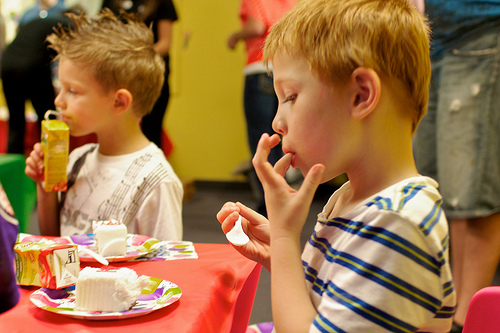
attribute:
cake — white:
[92, 219, 126, 256]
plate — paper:
[62, 234, 161, 261]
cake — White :
[70, 260, 142, 315]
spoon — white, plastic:
[222, 203, 259, 250]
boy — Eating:
[215, 1, 458, 331]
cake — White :
[65, 260, 147, 314]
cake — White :
[88, 211, 133, 259]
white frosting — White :
[71, 266, 136, 311]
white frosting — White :
[91, 217, 128, 255]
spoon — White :
[214, 205, 266, 256]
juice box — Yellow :
[16, 238, 76, 282]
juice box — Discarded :
[11, 235, 71, 295]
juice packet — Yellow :
[8, 221, 83, 294]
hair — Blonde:
[257, 2, 452, 189]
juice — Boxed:
[36, 112, 73, 194]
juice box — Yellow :
[35, 102, 85, 207]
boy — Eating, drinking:
[24, 9, 195, 252]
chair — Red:
[458, 260, 498, 324]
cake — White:
[71, 217, 151, 264]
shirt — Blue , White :
[305, 202, 447, 318]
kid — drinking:
[19, 39, 314, 330]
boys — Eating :
[23, 0, 462, 262]